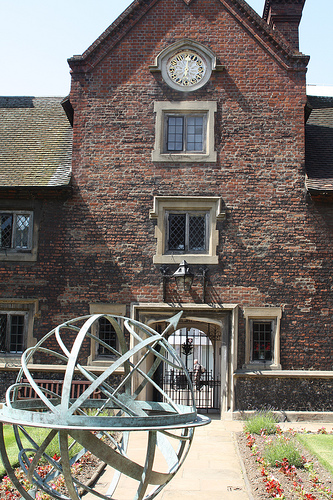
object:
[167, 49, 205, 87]
clock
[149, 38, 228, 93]
frame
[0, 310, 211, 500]
sculpture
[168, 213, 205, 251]
mesh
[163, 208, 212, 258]
window